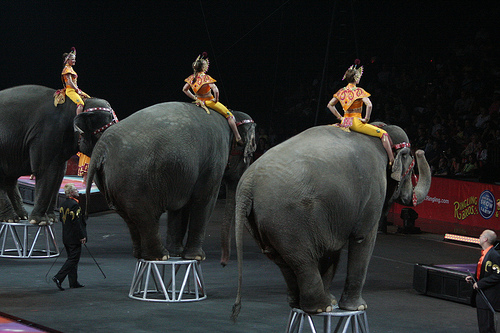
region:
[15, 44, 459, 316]
three elephants in a row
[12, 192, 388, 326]
elephants are standing on stands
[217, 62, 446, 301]
this is a elephant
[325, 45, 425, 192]
this is a woman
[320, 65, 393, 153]
woman with hands on her hips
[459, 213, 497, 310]
person looking at the elephant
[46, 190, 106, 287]
person wearing a black suit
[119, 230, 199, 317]
elephant stand is white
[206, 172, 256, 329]
this is a an elephant tail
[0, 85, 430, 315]
three elephants on stands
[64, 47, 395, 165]
three circus performers on the elephants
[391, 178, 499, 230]
red fence between ring and audience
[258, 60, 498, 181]
circus audience in the dark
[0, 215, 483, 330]
gray floor under the elephants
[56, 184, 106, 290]
elephant trainer between the elephants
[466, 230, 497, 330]
ring master on the right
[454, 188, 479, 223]
yellow Ringling Bros. logo.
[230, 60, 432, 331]
woman riding the elephant on the right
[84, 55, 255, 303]
the woman and elephant on the center stand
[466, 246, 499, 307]
a black suit coat on a man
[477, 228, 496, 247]
the bald head of a man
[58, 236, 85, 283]
black pants on a man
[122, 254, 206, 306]
a metal stand underneath an elephant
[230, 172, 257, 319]
a long tail on an elephant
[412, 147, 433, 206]
the trunk of an elephant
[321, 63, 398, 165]
a woman sitting on an elephant's back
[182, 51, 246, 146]
a woman in a yellow and red costume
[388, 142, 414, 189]
the ear of an elephant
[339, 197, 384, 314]
the front leg of an elephant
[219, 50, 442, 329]
this is an elephant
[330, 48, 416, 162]
woman sitting on elephant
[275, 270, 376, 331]
elephant standing on a stand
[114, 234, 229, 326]
elephant stand is white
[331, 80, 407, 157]
woman with yellow outfit on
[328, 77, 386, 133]
woman with arms on hips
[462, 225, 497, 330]
this is a man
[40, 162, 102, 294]
person looking at the elephant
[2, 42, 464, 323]
three elephants in a row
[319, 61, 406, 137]
A lady on top of an elephant.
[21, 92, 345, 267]
Three elephant in the circus.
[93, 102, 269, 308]
Elephant standing on the stool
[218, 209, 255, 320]
The elephant tail is long.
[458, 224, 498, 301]
The ring leader of the circus.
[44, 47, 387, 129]
Three women on elephants.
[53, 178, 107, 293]
Man standing with a stick.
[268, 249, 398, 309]
The elephant legs on the stool.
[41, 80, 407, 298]
Elephants perfoming and doing tricks.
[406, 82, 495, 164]
Audience watching the show.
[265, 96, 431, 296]
an elephant standing inside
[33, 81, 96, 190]
an elephant standing inside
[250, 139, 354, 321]
an elephant in the circus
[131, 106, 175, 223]
an elephant in the circus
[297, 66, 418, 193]
a woman sititng on the elephant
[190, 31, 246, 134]
a woman sittin gon the elephant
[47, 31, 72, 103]
a woman sitting on the elephant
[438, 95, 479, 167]
a person in the audience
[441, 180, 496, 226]
Ringling brothers sign on red banner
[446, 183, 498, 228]
Ringling brothers sign on red banner